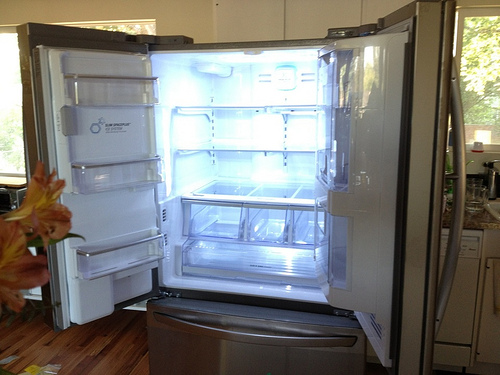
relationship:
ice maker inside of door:
[60, 96, 171, 189] [41, 37, 183, 322]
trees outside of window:
[467, 21, 497, 118] [408, 8, 498, 175]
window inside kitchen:
[408, 8, 498, 175] [13, 7, 498, 369]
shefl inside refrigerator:
[169, 42, 329, 121] [146, 30, 317, 342]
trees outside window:
[467, 21, 497, 118] [452, 12, 499, 155]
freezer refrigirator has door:
[27, 0, 474, 370] [15, 21, 165, 331]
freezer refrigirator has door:
[27, 0, 474, 370] [314, 0, 466, 375]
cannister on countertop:
[475, 157, 499, 195] [444, 194, 494, 236]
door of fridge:
[15, 21, 165, 331] [16, 0, 468, 374]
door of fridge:
[314, 0, 466, 375] [16, 0, 468, 374]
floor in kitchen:
[1, 308, 145, 374] [13, 7, 498, 369]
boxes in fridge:
[179, 180, 330, 248] [16, 0, 468, 374]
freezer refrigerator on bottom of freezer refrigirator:
[143, 300, 384, 372] [27, 0, 474, 370]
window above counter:
[408, 8, 498, 175] [443, 174, 484, 232]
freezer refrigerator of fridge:
[143, 300, 384, 372] [16, 0, 468, 374]